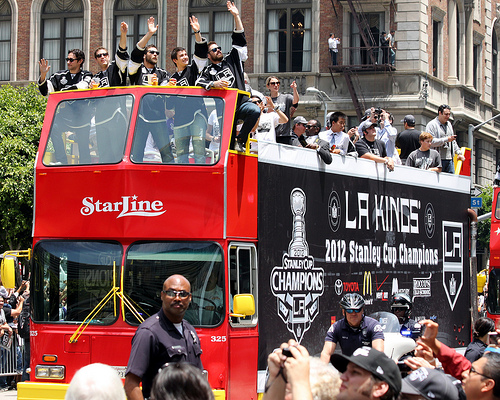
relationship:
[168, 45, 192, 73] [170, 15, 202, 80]
head of a man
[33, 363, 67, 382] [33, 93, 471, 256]
headlight of bus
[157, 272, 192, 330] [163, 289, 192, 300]
man wearing glasses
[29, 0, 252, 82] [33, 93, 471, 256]
hockey team standing on bus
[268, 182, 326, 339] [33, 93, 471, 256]
logo on side of bus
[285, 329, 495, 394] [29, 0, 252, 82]
spectators watching hockey team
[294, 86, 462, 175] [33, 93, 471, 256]
people standing on bus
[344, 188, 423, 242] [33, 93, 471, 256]
words on side bus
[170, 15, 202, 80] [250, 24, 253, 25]
man looking around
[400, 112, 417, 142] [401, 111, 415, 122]
man wearing a hat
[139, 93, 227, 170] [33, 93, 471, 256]
window on side of bus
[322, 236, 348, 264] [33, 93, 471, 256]
"2012" alongside bus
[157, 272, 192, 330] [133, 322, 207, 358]
man wearing a uniform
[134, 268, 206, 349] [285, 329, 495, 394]
policeman watching crowd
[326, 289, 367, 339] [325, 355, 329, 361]
policeman riding bicycle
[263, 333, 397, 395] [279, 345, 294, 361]
person using a camera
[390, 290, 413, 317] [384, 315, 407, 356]
policeman riding motorcycle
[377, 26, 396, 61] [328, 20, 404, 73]
people standing on balcony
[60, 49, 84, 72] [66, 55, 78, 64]
man wearing glasses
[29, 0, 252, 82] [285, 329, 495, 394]
hockey team waving to crowd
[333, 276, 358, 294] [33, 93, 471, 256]
toyota advertisement on side of bus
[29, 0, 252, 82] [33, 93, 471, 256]
hockey team waving on bus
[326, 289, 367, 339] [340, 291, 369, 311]
officer wearing a helmet